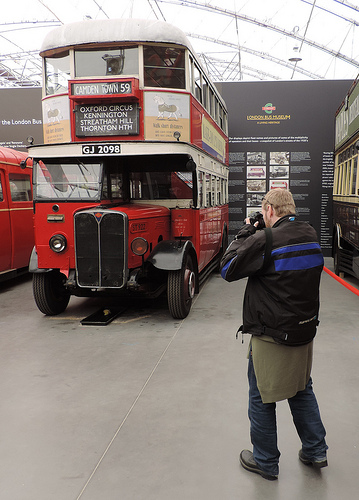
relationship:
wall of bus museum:
[2, 72, 359, 263] [0, 0, 358, 498]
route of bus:
[78, 105, 138, 134] [28, 16, 233, 322]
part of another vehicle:
[0, 142, 41, 295] [1, 143, 40, 292]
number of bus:
[79, 143, 122, 157] [28, 16, 233, 322]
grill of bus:
[71, 206, 128, 296] [28, 16, 233, 322]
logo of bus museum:
[258, 100, 276, 116] [0, 0, 358, 498]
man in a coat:
[218, 185, 331, 484] [220, 212, 322, 348]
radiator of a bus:
[69, 208, 131, 294] [28, 16, 233, 322]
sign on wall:
[241, 98, 299, 132] [2, 72, 359, 263]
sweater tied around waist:
[248, 330, 319, 409] [239, 306, 325, 348]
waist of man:
[239, 306, 325, 348] [218, 185, 331, 484]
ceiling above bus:
[0, 1, 358, 87] [28, 16, 233, 322]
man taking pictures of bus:
[218, 185, 331, 484] [28, 16, 233, 322]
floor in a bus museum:
[2, 253, 358, 499] [0, 0, 358, 498]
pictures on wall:
[245, 147, 290, 228] [2, 72, 359, 263]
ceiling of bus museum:
[0, 1, 358, 87] [0, 0, 358, 498]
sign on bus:
[68, 73, 145, 141] [28, 16, 233, 322]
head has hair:
[260, 185, 298, 217] [261, 190, 297, 223]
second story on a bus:
[36, 18, 233, 170] [28, 16, 233, 322]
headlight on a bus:
[127, 232, 152, 259] [28, 16, 233, 322]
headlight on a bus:
[45, 232, 70, 256] [28, 16, 233, 322]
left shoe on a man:
[239, 447, 284, 481] [218, 185, 331, 484]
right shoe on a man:
[297, 448, 331, 473] [218, 185, 331, 484]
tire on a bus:
[167, 249, 197, 320] [28, 16, 233, 322]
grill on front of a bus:
[71, 206, 128, 296] [28, 16, 233, 322]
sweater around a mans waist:
[248, 330, 319, 409] [239, 306, 325, 348]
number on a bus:
[79, 143, 122, 157] [28, 16, 233, 322]